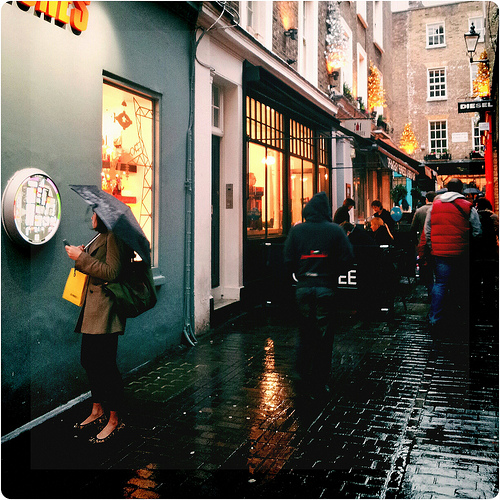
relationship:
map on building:
[3, 170, 62, 248] [0, 0, 197, 440]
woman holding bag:
[61, 207, 129, 446] [58, 267, 88, 306]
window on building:
[429, 116, 449, 156] [388, 0, 491, 192]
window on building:
[419, 63, 448, 103] [1, 1, 393, 446]